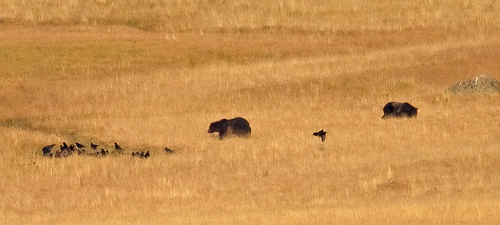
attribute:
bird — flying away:
[314, 130, 327, 145]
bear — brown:
[206, 116, 252, 139]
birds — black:
[34, 138, 159, 164]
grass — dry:
[3, 2, 496, 224]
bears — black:
[207, 101, 418, 138]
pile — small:
[446, 74, 498, 94]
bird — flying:
[311, 127, 328, 141]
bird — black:
[312, 125, 329, 139]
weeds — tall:
[1, 1, 498, 223]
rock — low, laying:
[444, 74, 499, 96]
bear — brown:
[381, 99, 421, 121]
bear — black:
[381, 101, 418, 118]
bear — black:
[207, 115, 252, 142]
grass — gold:
[12, 38, 493, 223]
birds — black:
[161, 144, 175, 155]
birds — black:
[111, 141, 122, 149]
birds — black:
[87, 137, 99, 148]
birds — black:
[41, 142, 56, 151]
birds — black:
[73, 140, 88, 148]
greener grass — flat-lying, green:
[41, 46, 107, 75]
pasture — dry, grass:
[6, 10, 484, 212]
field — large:
[1, 54, 499, 221]